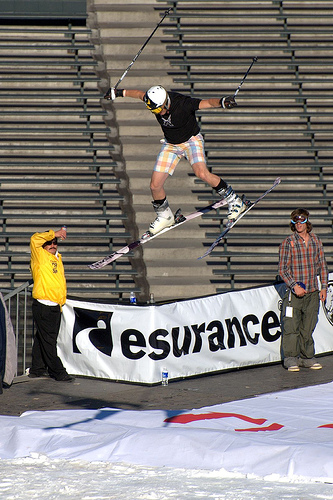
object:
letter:
[225, 317, 247, 349]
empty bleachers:
[0, 0, 333, 375]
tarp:
[114, 410, 328, 493]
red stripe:
[163, 412, 284, 432]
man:
[28, 229, 75, 383]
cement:
[0, 352, 333, 416]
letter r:
[191, 322, 205, 353]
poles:
[104, 85, 248, 236]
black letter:
[206, 320, 226, 351]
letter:
[121, 329, 146, 360]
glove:
[219, 95, 237, 109]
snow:
[0, 452, 333, 500]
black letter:
[242, 314, 260, 345]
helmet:
[143, 84, 169, 114]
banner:
[56, 272, 333, 383]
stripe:
[317, 424, 333, 429]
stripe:
[235, 422, 283, 432]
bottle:
[162, 368, 169, 387]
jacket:
[29, 229, 67, 314]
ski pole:
[233, 55, 259, 99]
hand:
[219, 94, 237, 109]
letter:
[172, 326, 191, 358]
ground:
[0, 352, 333, 500]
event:
[0, 0, 333, 500]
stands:
[0, 8, 119, 257]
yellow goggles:
[146, 99, 162, 114]